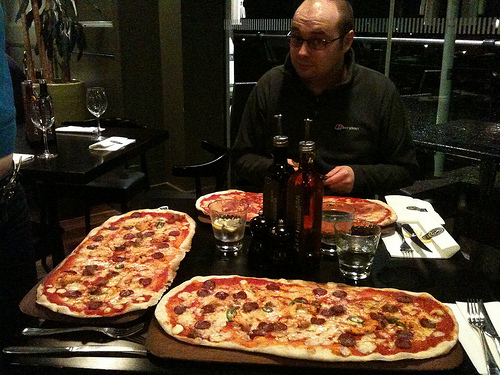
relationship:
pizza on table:
[192, 185, 400, 237] [1, 193, 499, 375]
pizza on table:
[32, 203, 201, 322] [1, 193, 499, 375]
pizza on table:
[147, 271, 463, 368] [1, 193, 499, 375]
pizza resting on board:
[192, 185, 400, 237] [195, 206, 398, 240]